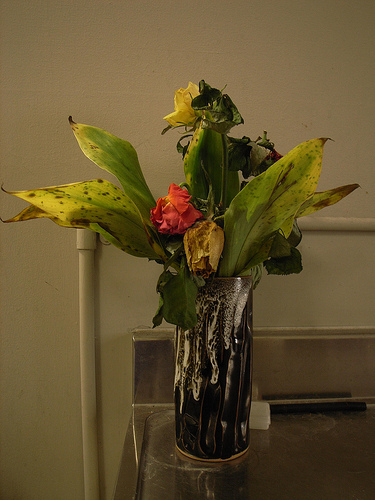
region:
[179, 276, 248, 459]
a black vase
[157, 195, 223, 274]
dying roses in a vase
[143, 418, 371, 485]
the black table the vase is sitting on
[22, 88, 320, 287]
leaves and flowers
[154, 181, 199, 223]
a pink rose in the vase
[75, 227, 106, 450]
a white pipe on the wall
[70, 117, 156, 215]
a green leaf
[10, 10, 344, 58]
a white wall behind the flowers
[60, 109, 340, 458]
some flowers on a table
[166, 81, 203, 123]
a yellow rose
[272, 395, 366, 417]
A BLACK OBJECT IS BEHIND THE VASE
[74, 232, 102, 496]
WHITE PIPE IS ON THE WALL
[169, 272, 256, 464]
VASE IS BLACK AND WHITE IN COLOR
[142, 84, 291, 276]
FLOWERS IN THE VASE ARE ROSES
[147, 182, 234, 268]
ROSES ARE DROOPING DOWN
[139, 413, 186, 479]
A WHITE RESIDUE IS ON THE TABLE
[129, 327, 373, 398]
TABLE HAS A SLASH GUARD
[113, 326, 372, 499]
TABLE IS SILVER IN COLOR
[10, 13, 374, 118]
WALL BEHIND VASE IS WHITE IN COLOR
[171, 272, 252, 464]
VASE IS ROUND IN SHAPE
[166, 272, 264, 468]
a vase color white and brown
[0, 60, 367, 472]
plants in a vase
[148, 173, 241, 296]
a red flower in a vase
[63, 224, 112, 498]
a white pipe on wall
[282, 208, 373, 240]
a pipe behind a vase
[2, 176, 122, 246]
leaves are withered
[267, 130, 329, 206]
leaves are withered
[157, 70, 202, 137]
a yellow flower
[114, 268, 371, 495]
a vase over a counter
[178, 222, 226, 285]
the leave is withered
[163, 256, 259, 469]
a vase on a counter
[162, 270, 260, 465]
the vase shape is cylindrical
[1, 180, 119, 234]
leaves of plant are dry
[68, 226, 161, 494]
a tube next a counter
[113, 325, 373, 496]
counter is color silver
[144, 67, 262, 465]
yellow and red flowers in a vase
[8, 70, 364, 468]
plants in a vase are drying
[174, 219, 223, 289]
the flower is dry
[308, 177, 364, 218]
tip of leave is brown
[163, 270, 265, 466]
vase has white stripes